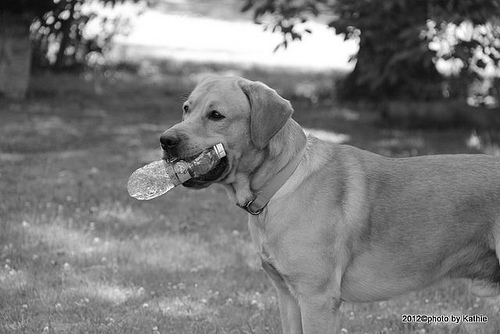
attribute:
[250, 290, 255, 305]
mark — white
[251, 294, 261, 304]
mark — white, spotted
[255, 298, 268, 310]
mark — white, spotted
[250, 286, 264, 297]
mark — spotted, white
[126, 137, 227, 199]
bottle — plastic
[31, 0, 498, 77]
road — sunshiny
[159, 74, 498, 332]
lab — yellow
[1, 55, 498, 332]
grass — long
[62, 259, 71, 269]
flower — white, small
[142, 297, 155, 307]
mark — white, spotted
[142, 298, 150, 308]
mark — spotted, white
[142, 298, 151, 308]
mark — white, spotted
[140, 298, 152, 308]
mark — spotted, white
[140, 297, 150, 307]
mark — spotted, white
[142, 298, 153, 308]
mark — white, spotted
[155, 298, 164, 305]
mark — white, spotted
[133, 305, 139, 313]
mark — spotted, white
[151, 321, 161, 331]
mark — white, spotted